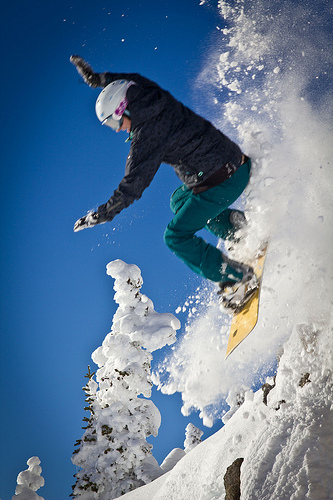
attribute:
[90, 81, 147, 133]
helmet — white, snowboarding, one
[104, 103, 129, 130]
goggles — snow, blue, purple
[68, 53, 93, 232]
gloves — snow, winter, black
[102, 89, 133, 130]
goggles — white, strapped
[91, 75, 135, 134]
helmet — snow, white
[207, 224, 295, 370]
snowboard — tan, wooden, floating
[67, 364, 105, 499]
pine tree — snow covered, one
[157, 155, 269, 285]
pants — snow, green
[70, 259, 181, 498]
tree — pine, snow covered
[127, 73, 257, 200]
jacket — snow, down, black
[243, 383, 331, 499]
snow — white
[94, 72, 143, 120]
helmet — white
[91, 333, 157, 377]
tree — snow covered, pine